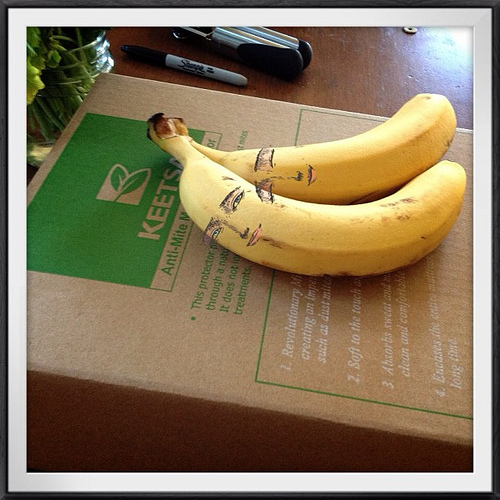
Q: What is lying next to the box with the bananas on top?
A: A black sharpie.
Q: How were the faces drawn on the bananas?
A: With a sharpie.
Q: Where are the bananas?
A: On top of a box.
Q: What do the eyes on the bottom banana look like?
A: They are open.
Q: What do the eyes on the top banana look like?
A: They are closed.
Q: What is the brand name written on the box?
A: Keetsa.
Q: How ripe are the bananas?
A: Ripe.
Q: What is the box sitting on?
A: A table.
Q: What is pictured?
A: Bananas.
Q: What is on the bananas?
A: Drawing of a face.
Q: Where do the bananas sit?
A: On a box.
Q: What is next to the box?
A: A black marker.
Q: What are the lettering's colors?
A: Green and white.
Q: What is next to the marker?
A: A stapler.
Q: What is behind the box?
A: A green plant.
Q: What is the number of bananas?
A: Two.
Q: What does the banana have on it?
A: Faces.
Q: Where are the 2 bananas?
A: On box.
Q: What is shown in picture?
A: Desk, box and bananas.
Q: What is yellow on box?
A: 2 bananas.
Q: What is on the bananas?
A: Drawn faces.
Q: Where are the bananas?
A: On box.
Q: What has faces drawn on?
A: Bananas.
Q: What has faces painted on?
A: Bananas.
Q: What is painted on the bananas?
A: Faces.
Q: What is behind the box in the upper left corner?
A: Vase.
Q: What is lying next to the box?
A: A Sharpie.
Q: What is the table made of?
A: Wood.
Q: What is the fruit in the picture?
A: Banana.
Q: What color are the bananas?
A: Yellow.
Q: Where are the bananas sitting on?
A: Box.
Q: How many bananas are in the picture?
A: Two.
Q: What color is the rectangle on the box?
A: Green.